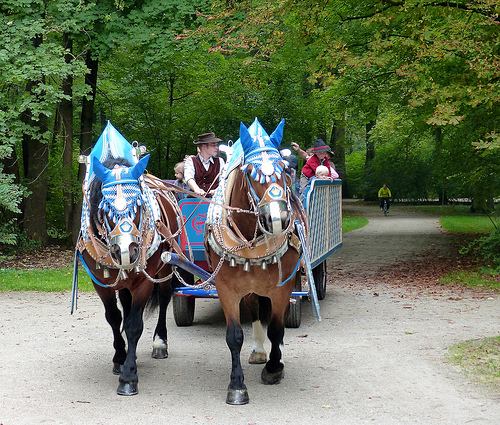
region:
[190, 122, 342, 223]
the horse's head is blue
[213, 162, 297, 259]
the horse's head is blue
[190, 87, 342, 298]
the horse's head is blue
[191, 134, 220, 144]
Brown head on a white man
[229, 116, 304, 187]
Horse wearing a blue hat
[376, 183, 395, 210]
Man wearing green riding bike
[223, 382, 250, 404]
Front right horse hoof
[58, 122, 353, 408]
Two horses pulling wagon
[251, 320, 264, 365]
Horse's back leg is white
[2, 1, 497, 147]
Trees in background of scene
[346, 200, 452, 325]
Path covered with leaves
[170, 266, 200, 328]
Wheel of wagon is round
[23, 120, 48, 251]
Tree trunk in background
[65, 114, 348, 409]
a cart led by two festive looking horses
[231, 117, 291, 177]
a colorful headdress on a horse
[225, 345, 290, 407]
a horse's hoofs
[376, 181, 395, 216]
a person riding a bicycle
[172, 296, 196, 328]
the wheel of a cart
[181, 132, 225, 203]
a man driving a horse led cart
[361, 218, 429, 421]
a dirt trail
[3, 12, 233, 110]
several lush trees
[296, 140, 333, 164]
a child standing in a cart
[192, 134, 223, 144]
a man's hat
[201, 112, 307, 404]
A brown horse dragging a cart full of people.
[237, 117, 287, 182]
A blue hat on top of the horse's head.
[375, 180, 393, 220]
A cyclist riding in the middle of the street.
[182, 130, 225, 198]
A white man operating the cart.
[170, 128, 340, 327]
A beautiful multicolored cart full of people.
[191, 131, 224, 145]
A brown hat on top of a white man.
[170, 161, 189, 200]
A little child looking to the right.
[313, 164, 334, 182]
A toddler who put his hands on the edge.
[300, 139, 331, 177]
A little kid wearing a red sweater.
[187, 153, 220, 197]
A nice brown sleeveless jacket.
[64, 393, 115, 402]
small spot on ground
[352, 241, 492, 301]
red leaves on the ground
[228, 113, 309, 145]
blue ears on horse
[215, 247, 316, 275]
silver bells in front of horse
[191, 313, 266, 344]
black color on horse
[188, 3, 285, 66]
gold leaves on tree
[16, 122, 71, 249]
large black tree trunk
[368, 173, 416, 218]
man riding bike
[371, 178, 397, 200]
man wearing green jacket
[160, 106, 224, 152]
brown hat on man's head